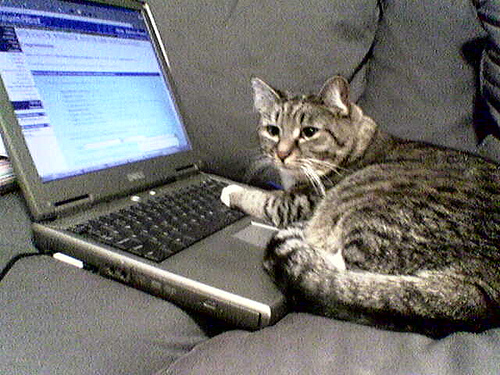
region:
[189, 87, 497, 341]
cat on a laptop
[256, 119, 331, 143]
cat with green eyes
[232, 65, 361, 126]
cat with perked ears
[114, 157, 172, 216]
silver dell laptop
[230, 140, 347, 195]
cat with long whiskers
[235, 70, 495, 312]
cat laying on a laptop and sofa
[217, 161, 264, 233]
cat paw on a keyboard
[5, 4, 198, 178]
computer screen with the power on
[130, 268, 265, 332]
DVD player on a laptop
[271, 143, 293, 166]
cat with pink nose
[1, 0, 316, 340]
A laptop in the foreground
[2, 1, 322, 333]
Laptop is gray in color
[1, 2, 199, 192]
The laptop screen is on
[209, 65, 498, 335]
A cat in the foreground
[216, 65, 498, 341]
A cat is laying down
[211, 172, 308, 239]
Cat's paw is on the laptop keyboard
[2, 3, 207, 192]
The laptop screen is on a webpage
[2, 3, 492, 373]
Photo was taken indoors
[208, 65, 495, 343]
The cat's fur is brown in color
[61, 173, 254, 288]
Laptop keys are dark gray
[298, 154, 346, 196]
Whiskers on the cat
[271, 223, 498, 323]
The tail of the cat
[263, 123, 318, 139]
The eyes of the cat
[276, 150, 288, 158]
The nose of the cat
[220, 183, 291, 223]
The front leg of the cat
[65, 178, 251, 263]
A keyboard on the laptop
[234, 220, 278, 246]
A mouse on the laptop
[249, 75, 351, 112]
The ears of the cat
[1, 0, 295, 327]
A laptop by the cat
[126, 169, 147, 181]
A Dell logo on the laptop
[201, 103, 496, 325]
cat is near laptop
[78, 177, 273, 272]
laptop has black keyboard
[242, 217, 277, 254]
laptop has grey touchpad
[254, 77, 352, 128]
cat has grey ears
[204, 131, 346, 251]
grey and white paws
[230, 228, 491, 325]
grey and black tail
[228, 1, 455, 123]
grey cushion behind cat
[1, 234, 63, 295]
black cord near laptop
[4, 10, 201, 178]
laptop monitor is on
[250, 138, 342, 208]
cat has white whiskers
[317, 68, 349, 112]
ear of the cat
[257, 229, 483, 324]
tail of the cat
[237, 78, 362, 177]
head of the cat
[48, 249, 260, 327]
side of the laptop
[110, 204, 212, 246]
keyboard on the laptop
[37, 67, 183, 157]
screen of the laptop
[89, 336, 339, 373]
cushion on the couch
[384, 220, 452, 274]
stripes on the cat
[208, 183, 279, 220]
paw of the cat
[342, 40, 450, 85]
back of the couch